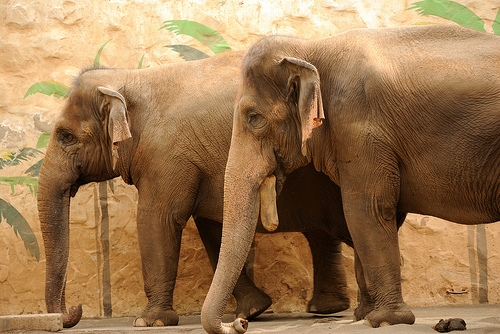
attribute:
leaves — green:
[156, 11, 235, 56]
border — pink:
[278, 52, 324, 121]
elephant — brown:
[204, 26, 499, 331]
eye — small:
[244, 109, 268, 129]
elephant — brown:
[13, 26, 236, 307]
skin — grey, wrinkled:
[381, 94, 443, 142]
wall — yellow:
[0, 2, 499, 316]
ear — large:
[95, 85, 132, 172]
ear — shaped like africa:
[296, 75, 349, 172]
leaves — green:
[0, 0, 498, 258]